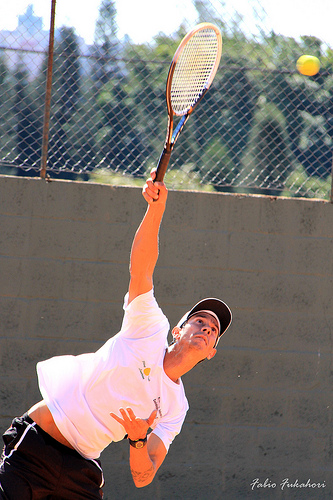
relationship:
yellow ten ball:
[302, 61, 310, 69] [297, 52, 322, 76]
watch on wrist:
[126, 437, 154, 453] [121, 434, 152, 456]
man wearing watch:
[36, 170, 242, 495] [126, 437, 154, 453]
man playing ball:
[36, 170, 242, 495] [296, 55, 323, 77]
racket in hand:
[128, 16, 227, 191] [134, 161, 168, 209]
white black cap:
[112, 371, 122, 390] [188, 295, 236, 328]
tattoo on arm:
[138, 255, 152, 267] [123, 170, 167, 299]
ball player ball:
[296, 55, 323, 77] [297, 52, 322, 76]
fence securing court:
[7, 10, 331, 185] [5, 172, 331, 380]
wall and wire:
[3, 175, 329, 390] [65, 53, 157, 159]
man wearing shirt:
[0, 167, 230, 500] [39, 351, 180, 431]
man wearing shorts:
[0, 167, 230, 500] [8, 410, 103, 500]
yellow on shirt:
[302, 61, 310, 69] [39, 351, 180, 431]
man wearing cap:
[36, 170, 242, 495] [177, 297, 233, 349]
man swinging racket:
[36, 170, 242, 495] [128, 16, 227, 191]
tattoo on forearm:
[138, 255, 152, 267] [128, 200, 167, 257]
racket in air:
[128, 16, 227, 191] [235, 87, 328, 236]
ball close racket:
[297, 52, 322, 76] [128, 16, 227, 191]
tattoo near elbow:
[138, 255, 152, 267] [123, 259, 175, 273]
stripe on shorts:
[13, 428, 25, 455] [8, 410, 103, 500]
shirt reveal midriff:
[39, 351, 180, 431] [21, 398, 65, 444]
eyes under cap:
[191, 317, 208, 327] [188, 295, 236, 328]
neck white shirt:
[157, 339, 181, 391] [39, 351, 180, 431]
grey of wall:
[192, 222, 223, 249] [3, 175, 329, 390]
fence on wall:
[7, 10, 331, 185] [3, 175, 329, 390]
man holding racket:
[36, 170, 242, 495] [128, 16, 227, 191]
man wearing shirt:
[36, 170, 242, 495] [39, 351, 180, 431]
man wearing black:
[36, 170, 242, 495] [30, 464, 49, 492]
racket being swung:
[128, 16, 227, 191] [116, 124, 174, 323]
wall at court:
[3, 175, 329, 390] [5, 172, 331, 380]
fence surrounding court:
[7, 10, 331, 185] [5, 172, 331, 380]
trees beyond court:
[243, 112, 287, 192] [5, 172, 331, 380]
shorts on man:
[8, 410, 103, 500] [0, 167, 230, 500]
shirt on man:
[39, 351, 180, 431] [0, 167, 230, 500]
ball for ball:
[297, 52, 322, 76] [296, 55, 323, 77]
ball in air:
[297, 52, 322, 76] [235, 87, 328, 236]